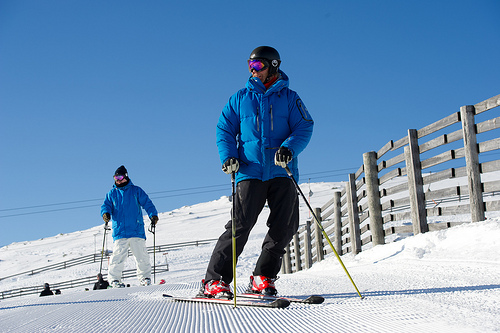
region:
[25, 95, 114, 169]
The sky is blue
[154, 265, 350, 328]
The person is skiing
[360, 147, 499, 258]
The fence is wooden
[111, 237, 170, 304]
Person has on white pants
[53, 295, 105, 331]
The snow is white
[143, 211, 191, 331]
The person has ski poles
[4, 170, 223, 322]
Power lines in the back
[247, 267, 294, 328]
The ski boots are red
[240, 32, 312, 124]
Person has on a helmet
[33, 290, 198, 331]
Tracks in the snow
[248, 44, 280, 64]
black helmet on a persons head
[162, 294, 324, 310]
long skis on a persons feet in the snow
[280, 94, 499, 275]
long large wooden fence in the snow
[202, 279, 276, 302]
red shoes on a man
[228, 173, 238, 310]
long metal skiing stick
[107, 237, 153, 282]
baggy white pants on a person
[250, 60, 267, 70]
purple goggles on a person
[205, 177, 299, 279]
black pants on a person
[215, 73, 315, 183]
large fluffy blue coat on a person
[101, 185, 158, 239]
big blue coat on a person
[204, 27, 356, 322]
The first skier wearing a blue jacket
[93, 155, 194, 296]
the second skier wearing a blue jacket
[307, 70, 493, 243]
a wooden fence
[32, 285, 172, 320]
white snow on the ground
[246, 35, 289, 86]
a black helmet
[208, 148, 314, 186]
a pair of black gloves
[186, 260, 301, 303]
a pair of red ski shoes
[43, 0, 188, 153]
a clear blue sky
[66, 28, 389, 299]
two skiers wearing blue jackets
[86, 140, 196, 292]
the skier wearing white pants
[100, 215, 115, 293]
The left ski pole of the skier wearing white pants.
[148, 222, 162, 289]
The right ski pole of the person wearing white pants.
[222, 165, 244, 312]
The left ski pole of the skier in black pants.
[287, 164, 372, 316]
The right ski pole of the skier wearing black pants.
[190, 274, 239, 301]
The left red ski boot.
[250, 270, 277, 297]
The right red ski boot.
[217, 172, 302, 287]
The black pants the skier is wearing.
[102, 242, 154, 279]
The white pants the skier is wearing.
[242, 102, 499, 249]
The wooden post fence on the right.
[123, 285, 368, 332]
The snow lines in front of the skier in red ski boots.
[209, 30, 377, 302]
The person is wearing goggles.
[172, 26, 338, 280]
The person is wearing blue.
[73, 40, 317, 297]
Both people are wearing blue.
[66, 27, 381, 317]
Both people are skiing.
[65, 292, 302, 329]
Tracks in the snow.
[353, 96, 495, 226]
A wooden fence.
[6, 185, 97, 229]
Wires can be seen in the background.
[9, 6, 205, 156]
The sky is clear and blue.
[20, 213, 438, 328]
A lot of snow is on the ground.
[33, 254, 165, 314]
Other people are in the background.